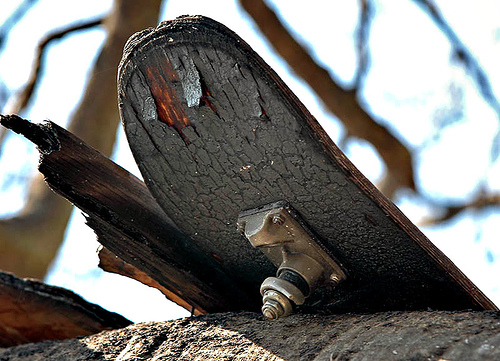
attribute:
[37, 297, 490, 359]
wood — piece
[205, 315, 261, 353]
wood — piece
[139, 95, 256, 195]
wood — burnt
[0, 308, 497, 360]
wood — piece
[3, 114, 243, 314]
wood — jagged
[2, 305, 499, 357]
material — gray, burnt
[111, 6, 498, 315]
wood — burnt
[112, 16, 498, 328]
skateboard — burnt, black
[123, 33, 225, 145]
paint — charred, peeling, burnt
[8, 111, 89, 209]
wood — broken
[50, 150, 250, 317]
wood — burnt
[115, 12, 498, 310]
board's paint — cracked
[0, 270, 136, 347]
wood — burnt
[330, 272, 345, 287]
bolt — small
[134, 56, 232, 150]
paint — cracked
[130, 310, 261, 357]
wood — burnt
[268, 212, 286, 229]
silver bolt — small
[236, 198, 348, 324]
truck — silver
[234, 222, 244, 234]
bolt — small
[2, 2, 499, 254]
tree branches — leafless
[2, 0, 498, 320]
sky — bright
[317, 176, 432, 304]
wood — burnt 